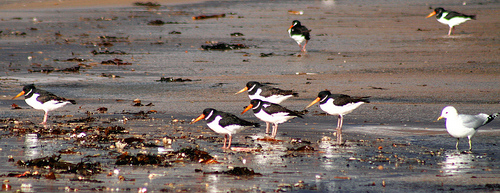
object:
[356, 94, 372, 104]
black tail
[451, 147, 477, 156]
two feet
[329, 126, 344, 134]
two feet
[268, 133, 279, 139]
two feet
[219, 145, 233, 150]
two feet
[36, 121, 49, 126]
two feet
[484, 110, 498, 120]
tail feathers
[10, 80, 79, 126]
bird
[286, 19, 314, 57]
bird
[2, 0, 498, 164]
beach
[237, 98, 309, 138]
bird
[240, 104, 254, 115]
beak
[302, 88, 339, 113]
bill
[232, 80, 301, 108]
bird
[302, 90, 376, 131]
bird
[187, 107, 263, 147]
bird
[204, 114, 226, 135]
breast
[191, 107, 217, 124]
head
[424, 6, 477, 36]
bird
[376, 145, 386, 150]
orange object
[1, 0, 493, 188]
ground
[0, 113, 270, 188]
debris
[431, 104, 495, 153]
bird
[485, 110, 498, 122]
black tail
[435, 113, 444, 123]
beak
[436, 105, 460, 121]
head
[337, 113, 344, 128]
legs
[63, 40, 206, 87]
debris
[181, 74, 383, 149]
group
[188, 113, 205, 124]
beaks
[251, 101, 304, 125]
bodies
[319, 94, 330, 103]
stripe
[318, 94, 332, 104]
throat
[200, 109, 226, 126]
streak